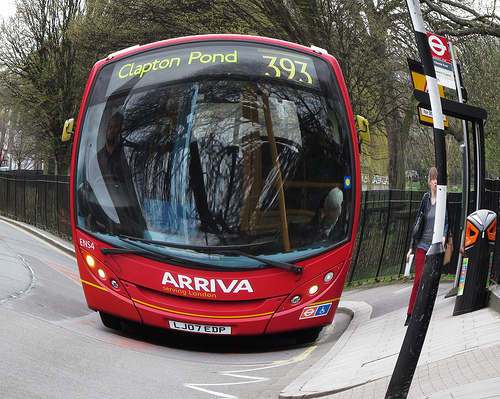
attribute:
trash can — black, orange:
[455, 210, 497, 315]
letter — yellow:
[206, 291, 216, 301]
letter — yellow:
[210, 49, 229, 66]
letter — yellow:
[223, 42, 242, 79]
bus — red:
[76, 32, 351, 360]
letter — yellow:
[168, 53, 183, 74]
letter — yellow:
[177, 50, 221, 70]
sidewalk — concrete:
[343, 280, 484, 387]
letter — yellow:
[198, 52, 213, 66]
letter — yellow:
[117, 60, 128, 79]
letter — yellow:
[125, 61, 132, 73]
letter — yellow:
[134, 63, 143, 75]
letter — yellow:
[139, 60, 151, 76]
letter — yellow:
[149, 55, 159, 69]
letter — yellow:
[159, 58, 166, 70]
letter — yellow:
[168, 56, 179, 71]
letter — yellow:
[186, 48, 200, 68]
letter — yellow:
[198, 50, 209, 65]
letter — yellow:
[214, 51, 222, 61]